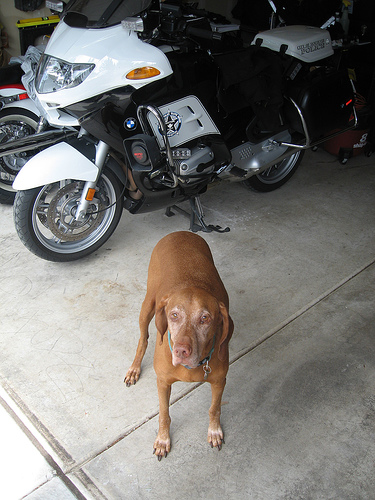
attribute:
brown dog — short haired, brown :
[125, 227, 241, 460]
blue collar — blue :
[161, 325, 227, 380]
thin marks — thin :
[29, 329, 110, 408]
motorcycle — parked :
[15, 8, 349, 265]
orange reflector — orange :
[84, 184, 97, 205]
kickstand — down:
[163, 188, 247, 239]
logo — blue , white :
[122, 115, 140, 131]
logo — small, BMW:
[121, 115, 138, 132]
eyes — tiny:
[166, 307, 210, 323]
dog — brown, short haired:
[123, 230, 236, 461]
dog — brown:
[155, 282, 230, 382]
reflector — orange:
[84, 186, 96, 202]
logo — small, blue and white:
[121, 115, 138, 130]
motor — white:
[145, 90, 224, 154]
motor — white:
[151, 90, 222, 145]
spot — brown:
[65, 264, 140, 329]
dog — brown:
[131, 229, 238, 455]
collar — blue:
[160, 327, 217, 373]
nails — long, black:
[149, 441, 171, 460]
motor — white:
[33, 20, 169, 130]